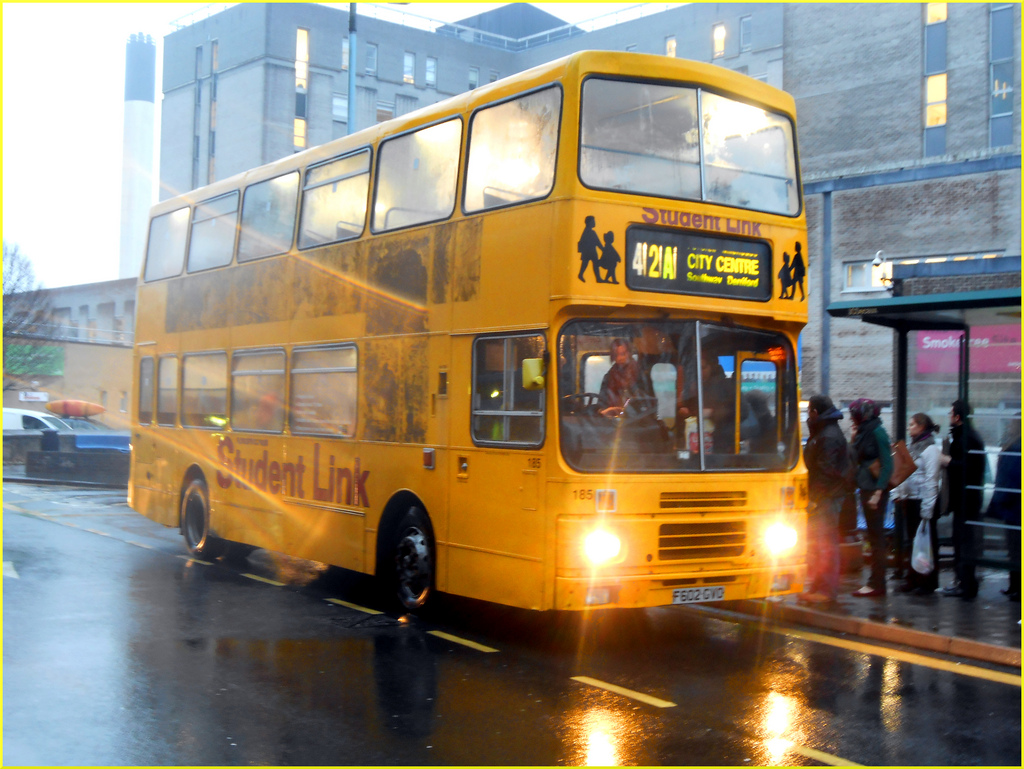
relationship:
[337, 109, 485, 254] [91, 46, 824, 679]
window on bus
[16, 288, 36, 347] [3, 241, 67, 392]
leaves on leaves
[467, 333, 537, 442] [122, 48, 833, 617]
window on bus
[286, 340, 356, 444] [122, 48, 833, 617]
window on bus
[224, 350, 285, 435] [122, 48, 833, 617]
window on bus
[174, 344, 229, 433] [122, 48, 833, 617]
window on bus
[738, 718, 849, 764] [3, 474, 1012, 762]
line on road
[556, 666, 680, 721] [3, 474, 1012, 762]
line on road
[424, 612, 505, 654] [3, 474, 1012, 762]
line on road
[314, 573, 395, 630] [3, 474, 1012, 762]
line on road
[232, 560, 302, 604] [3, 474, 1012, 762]
line on road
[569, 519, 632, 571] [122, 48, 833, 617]
right light on bus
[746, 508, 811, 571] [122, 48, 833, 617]
left headlight on bus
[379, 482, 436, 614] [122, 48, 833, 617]
wheel on bus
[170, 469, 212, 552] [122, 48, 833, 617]
wheel on bus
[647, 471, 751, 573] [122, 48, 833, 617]
grate on bus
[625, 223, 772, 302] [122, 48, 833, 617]
lcd on bus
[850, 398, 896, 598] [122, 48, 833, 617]
person waiting to board bus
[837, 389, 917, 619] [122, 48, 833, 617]
person waiting to board bus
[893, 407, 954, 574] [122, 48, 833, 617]
person waiting to board bus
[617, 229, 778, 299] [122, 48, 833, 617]
lcd on bus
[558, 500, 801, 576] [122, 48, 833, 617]
lights on bus